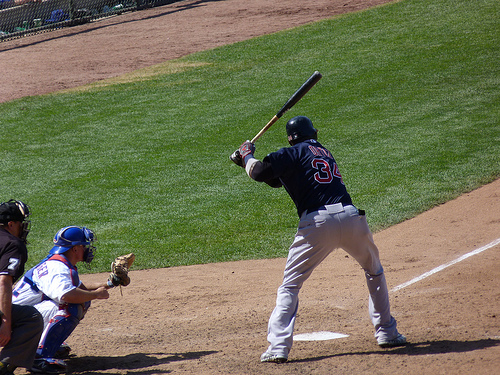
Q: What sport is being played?
A: Baseball.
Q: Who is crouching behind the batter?
A: Catcher and umpire.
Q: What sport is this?
A: Baseball.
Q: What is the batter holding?
A: Baseball bat.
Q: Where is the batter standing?
A: Baseball field.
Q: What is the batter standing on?
A: Home Plate.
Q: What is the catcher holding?
A: Catcher's mitt.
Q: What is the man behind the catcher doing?
A: Umping.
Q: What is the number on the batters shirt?
A: 34.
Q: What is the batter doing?
A: Playing baseball.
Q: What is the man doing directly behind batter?
A: Catching.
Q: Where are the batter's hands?
A: On the bat.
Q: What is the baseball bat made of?
A: Wood.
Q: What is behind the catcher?
A: The umpire.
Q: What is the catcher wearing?
A: A white uniform.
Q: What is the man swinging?
A: A baseball bat.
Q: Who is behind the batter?
A: A catcher.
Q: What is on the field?
A: Short green grass.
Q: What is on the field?
A: Green grass.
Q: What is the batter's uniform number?
A: 34.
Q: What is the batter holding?
A: A baseball bat.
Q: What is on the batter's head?
A: A helmet.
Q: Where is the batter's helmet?
A: On his head.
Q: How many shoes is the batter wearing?
A: Two.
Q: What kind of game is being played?
A: Baseball.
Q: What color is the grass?
A: Green.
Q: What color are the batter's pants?
A: White.